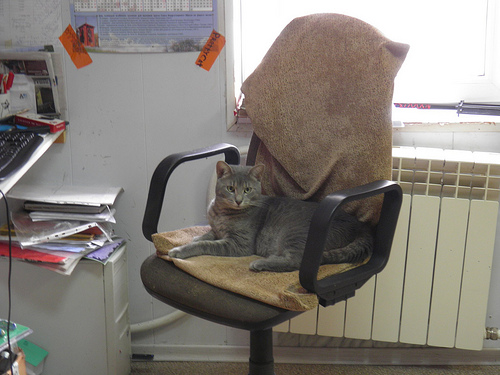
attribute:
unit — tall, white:
[13, 229, 138, 371]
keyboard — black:
[0, 127, 46, 177]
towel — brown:
[260, 10, 417, 192]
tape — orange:
[58, 23, 93, 69]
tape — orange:
[196, 27, 226, 71]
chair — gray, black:
[140, 35, 382, 361]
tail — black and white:
[251, 240, 371, 270]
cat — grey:
[169, 162, 372, 267]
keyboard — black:
[2, 126, 46, 191]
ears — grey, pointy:
[213, 157, 268, 181]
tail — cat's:
[318, 232, 373, 265]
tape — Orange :
[190, 28, 225, 69]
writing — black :
[190, 28, 222, 64]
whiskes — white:
[246, 192, 264, 208]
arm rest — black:
[140, 140, 242, 242]